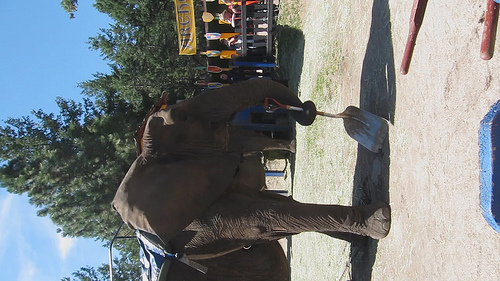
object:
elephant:
[115, 76, 393, 280]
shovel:
[261, 96, 394, 154]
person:
[218, 10, 237, 23]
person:
[223, 35, 242, 48]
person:
[218, 71, 237, 81]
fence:
[232, 2, 289, 70]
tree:
[0, 90, 171, 258]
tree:
[76, 63, 211, 105]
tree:
[86, 21, 201, 76]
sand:
[266, 2, 498, 280]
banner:
[172, 1, 199, 56]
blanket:
[134, 232, 211, 280]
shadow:
[347, 1, 396, 281]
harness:
[174, 246, 258, 275]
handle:
[399, 1, 428, 74]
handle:
[480, 1, 500, 58]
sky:
[0, 1, 137, 280]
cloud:
[58, 232, 77, 261]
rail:
[241, 0, 251, 60]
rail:
[266, 2, 275, 62]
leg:
[217, 190, 391, 241]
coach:
[109, 224, 145, 280]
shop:
[174, 1, 247, 95]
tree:
[52, 255, 142, 280]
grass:
[273, 0, 303, 33]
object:
[478, 100, 499, 231]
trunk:
[206, 76, 317, 133]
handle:
[263, 97, 289, 117]